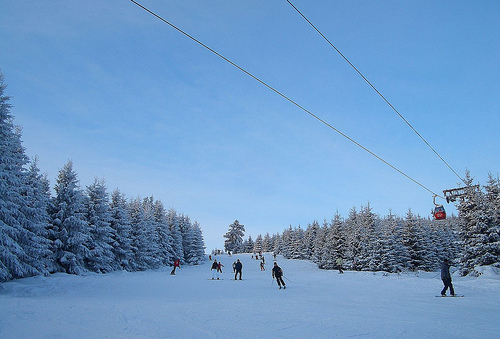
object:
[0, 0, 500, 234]
clouds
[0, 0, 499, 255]
sky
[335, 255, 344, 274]
people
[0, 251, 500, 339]
slope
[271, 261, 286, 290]
man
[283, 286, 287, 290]
skis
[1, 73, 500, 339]
snow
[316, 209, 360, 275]
trees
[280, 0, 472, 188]
cables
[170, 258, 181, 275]
person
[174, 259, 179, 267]
jacket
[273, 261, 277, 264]
hat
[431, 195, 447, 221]
ski lift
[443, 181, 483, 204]
ski lift pole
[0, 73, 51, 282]
snow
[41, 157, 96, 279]
tree